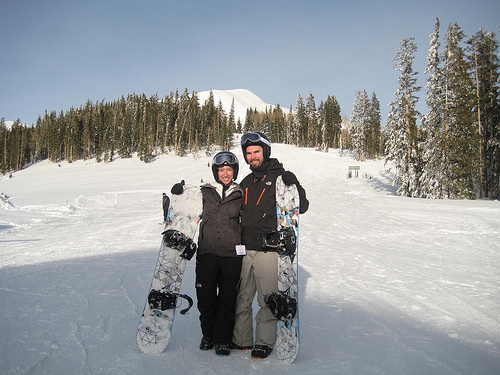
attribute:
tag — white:
[234, 242, 249, 256]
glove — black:
[170, 180, 184, 195]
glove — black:
[281, 170, 294, 182]